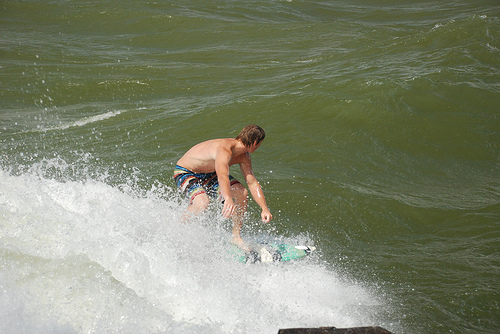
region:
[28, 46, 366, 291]
the man is surfing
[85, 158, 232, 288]
the waves are crashing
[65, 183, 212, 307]
the waves are white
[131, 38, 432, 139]
the ocean is green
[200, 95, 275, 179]
the man is shirtless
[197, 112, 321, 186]
the man has brown hair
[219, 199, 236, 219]
A man's right hand.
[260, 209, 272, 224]
A man's right hand.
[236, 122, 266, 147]
Brown hair of a surfer.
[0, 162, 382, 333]
White wave a man is surfing.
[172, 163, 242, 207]
Colorful shorts a man has on.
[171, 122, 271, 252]
A man surfing in colorful shorts.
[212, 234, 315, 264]
A green, white and black surfboard.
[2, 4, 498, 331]
Green water.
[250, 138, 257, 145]
A man's right ear.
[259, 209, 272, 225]
A man's left fist.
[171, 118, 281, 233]
man surfing in green water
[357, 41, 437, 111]
green and white ocean waves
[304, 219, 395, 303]
green and white ocean waves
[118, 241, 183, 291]
green and white ocean waves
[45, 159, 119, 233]
green and white ocean waves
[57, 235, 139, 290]
green and white ocean waves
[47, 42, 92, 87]
green and white ocean waves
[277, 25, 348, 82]
green and white ocean waves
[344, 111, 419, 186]
green and white ocean waves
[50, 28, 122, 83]
green and white ocean waves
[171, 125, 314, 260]
Man is surfing on a surfboard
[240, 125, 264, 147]
man has brown hair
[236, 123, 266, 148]
man has short hair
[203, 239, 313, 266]
surfboard is green, white, and black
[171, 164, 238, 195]
man has colorful swimming trunks on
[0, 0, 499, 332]
water is green and dark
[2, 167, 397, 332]
wave is white and frothy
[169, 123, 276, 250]
man is leaning over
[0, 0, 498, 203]
waves are in the background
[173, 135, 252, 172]
man has no shirt on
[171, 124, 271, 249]
A man bent over surfing with no shirt.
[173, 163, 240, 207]
Blue, yellow, red and black shorts on a man.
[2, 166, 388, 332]
White wave a man is surfing on.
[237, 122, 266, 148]
Brown hair of a man surfing.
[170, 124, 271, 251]
Man surfing with brown hair.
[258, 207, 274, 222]
A man's left hand.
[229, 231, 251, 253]
A man's left foot.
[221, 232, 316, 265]
Green, black and white surfboard.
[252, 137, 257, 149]
A man's right ear.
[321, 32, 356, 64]
green and white ocean waves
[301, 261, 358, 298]
green and white ocean waves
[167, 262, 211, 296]
green and white ocean waves